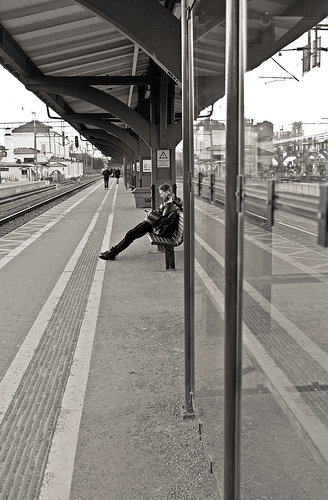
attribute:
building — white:
[12, 120, 83, 179]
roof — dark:
[11, 120, 48, 132]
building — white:
[0, 117, 84, 183]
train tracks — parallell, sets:
[0, 174, 103, 237]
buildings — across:
[17, 108, 77, 188]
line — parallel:
[39, 179, 120, 497]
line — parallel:
[1, 172, 113, 435]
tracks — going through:
[0, 172, 105, 226]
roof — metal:
[0, 0, 328, 156]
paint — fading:
[97, 202, 114, 210]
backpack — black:
[152, 208, 178, 237]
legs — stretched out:
[107, 221, 151, 260]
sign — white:
[148, 143, 174, 175]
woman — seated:
[95, 168, 180, 259]